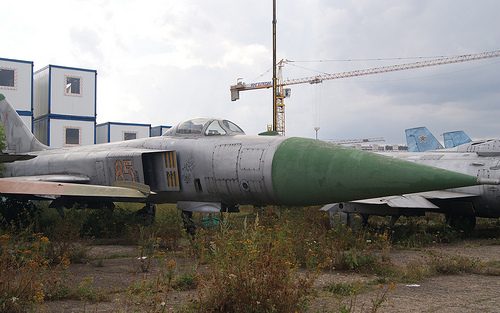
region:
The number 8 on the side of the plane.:
[109, 159, 126, 181]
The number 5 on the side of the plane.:
[121, 160, 139, 180]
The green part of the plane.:
[273, 128, 497, 225]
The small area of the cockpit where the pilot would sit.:
[173, 116, 238, 139]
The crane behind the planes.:
[223, 34, 499, 132]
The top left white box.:
[0, 56, 38, 105]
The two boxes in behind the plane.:
[37, 60, 98, 146]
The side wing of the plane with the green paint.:
[1, 158, 146, 202]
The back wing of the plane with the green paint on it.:
[1, 89, 41, 149]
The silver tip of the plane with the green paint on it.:
[478, 171, 499, 186]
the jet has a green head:
[268, 139, 470, 225]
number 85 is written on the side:
[7, 131, 174, 181]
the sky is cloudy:
[108, 51, 224, 114]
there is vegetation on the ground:
[190, 232, 388, 295]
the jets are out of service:
[59, 103, 494, 240]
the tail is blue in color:
[387, 118, 470, 145]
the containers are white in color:
[35, 71, 119, 141]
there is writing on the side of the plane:
[167, 156, 199, 183]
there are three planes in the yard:
[3, 109, 498, 236]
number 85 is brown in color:
[100, 162, 151, 189]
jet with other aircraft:
[23, 110, 490, 288]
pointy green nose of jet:
[252, 121, 482, 226]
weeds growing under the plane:
[66, 185, 451, 310]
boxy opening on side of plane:
[85, 131, 195, 201]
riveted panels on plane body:
[200, 127, 275, 199]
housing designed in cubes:
[5, 40, 150, 150]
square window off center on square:
[37, 60, 97, 116]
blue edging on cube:
[35, 56, 105, 121]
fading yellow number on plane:
[95, 147, 146, 187]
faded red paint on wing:
[1, 166, 73, 206]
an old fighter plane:
[12, 20, 477, 311]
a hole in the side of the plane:
[237, 175, 254, 197]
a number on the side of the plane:
[109, 150, 144, 184]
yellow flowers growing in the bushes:
[224, 229, 259, 264]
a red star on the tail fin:
[410, 129, 435, 152]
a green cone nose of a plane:
[279, 132, 484, 224]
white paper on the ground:
[136, 249, 155, 266]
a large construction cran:
[234, 35, 451, 126]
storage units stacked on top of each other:
[37, 59, 114, 142]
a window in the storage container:
[61, 67, 93, 99]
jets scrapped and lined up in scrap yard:
[0, 95, 498, 241]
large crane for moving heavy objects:
[227, 50, 495, 137]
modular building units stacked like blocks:
[0, 54, 178, 141]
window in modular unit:
[62, 76, 82, 95]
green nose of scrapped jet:
[271, 134, 498, 201]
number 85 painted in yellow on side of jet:
[110, 156, 137, 184]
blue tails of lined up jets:
[398, 123, 482, 147]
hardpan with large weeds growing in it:
[0, 209, 499, 310]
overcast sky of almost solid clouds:
[0, 0, 498, 140]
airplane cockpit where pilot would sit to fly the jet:
[168, 115, 238, 134]